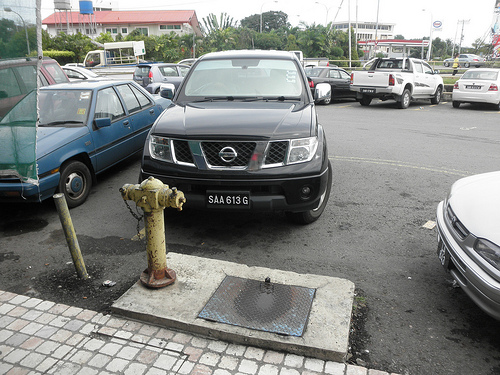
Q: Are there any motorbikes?
A: No, there are no motorbikes.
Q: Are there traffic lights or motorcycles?
A: No, there are no motorcycles or traffic lights.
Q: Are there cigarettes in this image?
A: No, there are no cigarettes.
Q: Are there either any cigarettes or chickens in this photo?
A: No, there are no cigarettes or chickens.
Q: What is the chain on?
A: The chain is on the hydrant.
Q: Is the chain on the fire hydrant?
A: Yes, the chain is on the fire hydrant.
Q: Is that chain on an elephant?
A: No, the chain is on the fire hydrant.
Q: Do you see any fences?
A: No, there are no fences.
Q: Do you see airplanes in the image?
A: No, there are no airplanes.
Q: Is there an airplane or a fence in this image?
A: No, there are no airplanes or fences.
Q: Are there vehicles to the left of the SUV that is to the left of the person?
A: Yes, there is a vehicle to the left of the SUV.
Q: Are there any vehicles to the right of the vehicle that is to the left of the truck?
A: No, the vehicle is to the left of the SUV.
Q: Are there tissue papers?
A: No, there are no tissue papers.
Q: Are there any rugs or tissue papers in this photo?
A: No, there are no tissue papers or rugs.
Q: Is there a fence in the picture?
A: No, there are no fences.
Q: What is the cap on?
A: The cap is on the hydrant.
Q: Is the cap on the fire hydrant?
A: Yes, the cap is on the fire hydrant.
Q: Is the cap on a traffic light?
A: No, the cap is on the fire hydrant.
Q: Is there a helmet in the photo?
A: No, there are no helmets.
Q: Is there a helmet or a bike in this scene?
A: No, there are no helmets or bikes.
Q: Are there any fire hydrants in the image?
A: Yes, there is a fire hydrant.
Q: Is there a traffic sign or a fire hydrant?
A: Yes, there is a fire hydrant.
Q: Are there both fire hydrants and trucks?
A: Yes, there are both a fire hydrant and a truck.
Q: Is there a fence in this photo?
A: No, there are no fences.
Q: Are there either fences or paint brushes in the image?
A: No, there are no fences or paint brushes.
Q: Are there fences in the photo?
A: No, there are no fences.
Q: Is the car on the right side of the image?
A: Yes, the car is on the right of the image.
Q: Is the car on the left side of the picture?
A: No, the car is on the right of the image.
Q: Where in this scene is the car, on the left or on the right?
A: The car is on the right of the image.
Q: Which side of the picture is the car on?
A: The car is on the right of the image.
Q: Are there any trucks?
A: Yes, there is a truck.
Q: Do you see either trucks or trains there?
A: Yes, there is a truck.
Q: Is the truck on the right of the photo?
A: Yes, the truck is on the right of the image.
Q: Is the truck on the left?
A: No, the truck is on the right of the image.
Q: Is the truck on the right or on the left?
A: The truck is on the right of the image.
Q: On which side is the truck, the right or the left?
A: The truck is on the right of the image.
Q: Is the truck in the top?
A: Yes, the truck is in the top of the image.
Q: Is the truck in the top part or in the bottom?
A: The truck is in the top of the image.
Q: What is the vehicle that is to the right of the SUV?
A: The vehicle is a truck.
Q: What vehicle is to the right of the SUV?
A: The vehicle is a truck.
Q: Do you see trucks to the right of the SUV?
A: Yes, there is a truck to the right of the SUV.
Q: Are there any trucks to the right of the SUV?
A: Yes, there is a truck to the right of the SUV.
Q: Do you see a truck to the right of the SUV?
A: Yes, there is a truck to the right of the SUV.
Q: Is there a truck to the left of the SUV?
A: No, the truck is to the right of the SUV.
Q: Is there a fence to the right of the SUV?
A: No, there is a truck to the right of the SUV.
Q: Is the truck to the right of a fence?
A: No, the truck is to the right of a SUV.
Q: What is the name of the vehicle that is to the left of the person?
A: The vehicle is a truck.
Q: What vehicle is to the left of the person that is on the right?
A: The vehicle is a truck.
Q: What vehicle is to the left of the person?
A: The vehicle is a truck.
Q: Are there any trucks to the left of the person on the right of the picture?
A: Yes, there is a truck to the left of the person.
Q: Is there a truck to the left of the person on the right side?
A: Yes, there is a truck to the left of the person.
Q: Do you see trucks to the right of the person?
A: No, the truck is to the left of the person.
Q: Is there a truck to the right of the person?
A: No, the truck is to the left of the person.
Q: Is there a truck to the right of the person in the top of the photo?
A: No, the truck is to the left of the person.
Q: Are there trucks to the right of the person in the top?
A: No, the truck is to the left of the person.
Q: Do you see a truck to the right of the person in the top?
A: No, the truck is to the left of the person.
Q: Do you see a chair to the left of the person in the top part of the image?
A: No, there is a truck to the left of the person.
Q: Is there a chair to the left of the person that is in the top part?
A: No, there is a truck to the left of the person.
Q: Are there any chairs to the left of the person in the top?
A: No, there is a truck to the left of the person.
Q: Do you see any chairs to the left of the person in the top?
A: No, there is a truck to the left of the person.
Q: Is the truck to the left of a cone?
A: No, the truck is to the left of a person.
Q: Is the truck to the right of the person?
A: No, the truck is to the left of the person.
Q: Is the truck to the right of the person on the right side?
A: No, the truck is to the left of the person.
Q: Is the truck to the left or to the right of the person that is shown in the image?
A: The truck is to the left of the person.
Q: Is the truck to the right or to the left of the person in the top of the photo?
A: The truck is to the left of the person.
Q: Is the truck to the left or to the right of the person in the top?
A: The truck is to the left of the person.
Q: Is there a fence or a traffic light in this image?
A: No, there are no fences or traffic lights.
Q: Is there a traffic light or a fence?
A: No, there are no fences or traffic lights.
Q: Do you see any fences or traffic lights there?
A: No, there are no fences or traffic lights.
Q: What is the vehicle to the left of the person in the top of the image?
A: The vehicle is a SUV.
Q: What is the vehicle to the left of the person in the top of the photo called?
A: The vehicle is a SUV.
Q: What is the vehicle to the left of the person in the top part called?
A: The vehicle is a SUV.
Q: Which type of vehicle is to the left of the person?
A: The vehicle is a SUV.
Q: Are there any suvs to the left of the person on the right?
A: Yes, there is a SUV to the left of the person.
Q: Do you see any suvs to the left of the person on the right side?
A: Yes, there is a SUV to the left of the person.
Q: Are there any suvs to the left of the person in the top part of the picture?
A: Yes, there is a SUV to the left of the person.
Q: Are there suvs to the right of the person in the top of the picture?
A: No, the SUV is to the left of the person.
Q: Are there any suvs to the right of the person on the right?
A: No, the SUV is to the left of the person.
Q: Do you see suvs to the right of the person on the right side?
A: No, the SUV is to the left of the person.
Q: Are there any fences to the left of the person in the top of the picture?
A: No, there is a SUV to the left of the person.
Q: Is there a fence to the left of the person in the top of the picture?
A: No, there is a SUV to the left of the person.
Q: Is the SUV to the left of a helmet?
A: No, the SUV is to the left of a person.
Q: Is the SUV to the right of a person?
A: No, the SUV is to the left of a person.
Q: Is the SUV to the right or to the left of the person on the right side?
A: The SUV is to the left of the person.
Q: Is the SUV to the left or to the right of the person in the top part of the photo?
A: The SUV is to the left of the person.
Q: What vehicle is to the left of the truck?
A: The vehicle is a SUV.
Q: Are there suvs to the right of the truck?
A: No, the SUV is to the left of the truck.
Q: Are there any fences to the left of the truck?
A: No, there is a SUV to the left of the truck.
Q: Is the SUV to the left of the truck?
A: Yes, the SUV is to the left of the truck.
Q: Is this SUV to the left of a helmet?
A: No, the SUV is to the left of the truck.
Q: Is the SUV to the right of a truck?
A: No, the SUV is to the left of a truck.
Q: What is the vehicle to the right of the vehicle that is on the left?
A: The vehicle is a SUV.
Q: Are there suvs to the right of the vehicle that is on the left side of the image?
A: Yes, there is a SUV to the right of the vehicle.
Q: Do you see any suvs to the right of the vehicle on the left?
A: Yes, there is a SUV to the right of the vehicle.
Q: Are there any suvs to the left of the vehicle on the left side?
A: No, the SUV is to the right of the vehicle.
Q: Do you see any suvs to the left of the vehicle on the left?
A: No, the SUV is to the right of the vehicle.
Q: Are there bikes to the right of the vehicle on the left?
A: No, there is a SUV to the right of the vehicle.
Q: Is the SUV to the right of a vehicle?
A: Yes, the SUV is to the right of a vehicle.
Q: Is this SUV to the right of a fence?
A: No, the SUV is to the right of a vehicle.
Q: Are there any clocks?
A: No, there are no clocks.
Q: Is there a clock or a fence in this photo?
A: No, there are no clocks or fences.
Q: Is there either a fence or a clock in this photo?
A: No, there are no clocks or fences.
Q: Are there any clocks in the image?
A: No, there are no clocks.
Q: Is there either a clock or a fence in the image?
A: No, there are no clocks or fences.